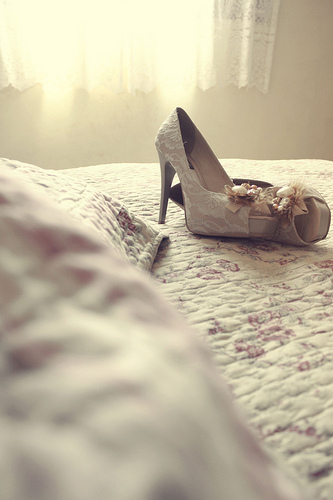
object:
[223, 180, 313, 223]
decoration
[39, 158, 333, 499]
sheet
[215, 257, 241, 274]
design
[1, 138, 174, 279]
pillow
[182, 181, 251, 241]
lace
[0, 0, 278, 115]
curtain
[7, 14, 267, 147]
sunlight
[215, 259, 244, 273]
print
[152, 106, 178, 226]
back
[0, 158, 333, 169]
edge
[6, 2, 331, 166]
wall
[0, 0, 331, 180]
background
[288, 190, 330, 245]
open toed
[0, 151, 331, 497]
blanket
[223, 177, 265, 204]
flower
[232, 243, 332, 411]
pattern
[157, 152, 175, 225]
four inch heel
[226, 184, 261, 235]
lace pattern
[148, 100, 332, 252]
high heels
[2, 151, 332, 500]
bed